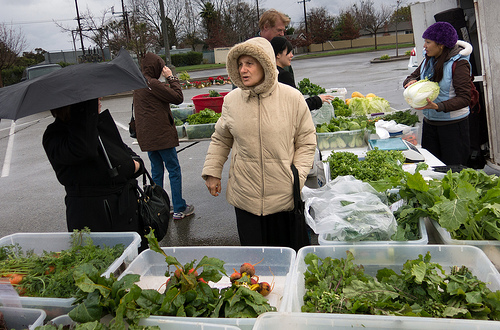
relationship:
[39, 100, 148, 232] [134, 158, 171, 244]
woman carrying a bags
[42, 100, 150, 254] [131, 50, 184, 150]
woman has coat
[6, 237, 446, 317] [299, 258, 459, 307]
bins filled with vegetables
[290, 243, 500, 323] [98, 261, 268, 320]
bins full of radish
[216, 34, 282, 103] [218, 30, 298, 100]
fur around hood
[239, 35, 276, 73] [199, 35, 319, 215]
hood of jacket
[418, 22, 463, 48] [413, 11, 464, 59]
cap on head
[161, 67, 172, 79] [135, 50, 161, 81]
hand raised to head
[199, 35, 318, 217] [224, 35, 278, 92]
jacket has hood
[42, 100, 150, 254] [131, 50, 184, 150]
woman wearing coat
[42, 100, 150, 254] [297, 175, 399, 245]
woman carrying bag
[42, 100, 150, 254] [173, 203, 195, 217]
woman wearing sneaker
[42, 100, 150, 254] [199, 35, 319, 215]
woman wearing jacket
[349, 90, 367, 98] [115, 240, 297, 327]
vegetable inside bin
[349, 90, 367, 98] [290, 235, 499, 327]
vegetable inside bin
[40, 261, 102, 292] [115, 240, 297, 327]
vegetable inside bin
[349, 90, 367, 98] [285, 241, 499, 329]
vegetable inside plastic bin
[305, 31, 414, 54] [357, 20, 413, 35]
fence in front of house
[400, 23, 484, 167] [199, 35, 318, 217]
woman wearing jacket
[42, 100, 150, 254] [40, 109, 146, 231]
woman wearing black jacket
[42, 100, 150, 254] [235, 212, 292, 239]
woman wearing pants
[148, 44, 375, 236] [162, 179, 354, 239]
woman wearing jeans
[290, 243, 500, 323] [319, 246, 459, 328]
bins of leaves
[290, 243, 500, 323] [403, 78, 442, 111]
bins of fruits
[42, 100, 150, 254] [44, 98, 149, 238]
woman wearing coat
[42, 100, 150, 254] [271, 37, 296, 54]
woman with black hair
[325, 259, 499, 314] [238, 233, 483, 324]
leaves in bin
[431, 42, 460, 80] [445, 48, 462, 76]
hair laying over shoulder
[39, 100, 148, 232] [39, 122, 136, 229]
woman wearing coat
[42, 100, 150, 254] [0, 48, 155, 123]
woman carrying umbrella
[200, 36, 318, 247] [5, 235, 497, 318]
woman at stand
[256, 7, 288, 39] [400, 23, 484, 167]
man talking to woman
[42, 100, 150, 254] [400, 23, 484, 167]
woman talking to woman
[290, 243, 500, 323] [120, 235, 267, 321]
bins of plants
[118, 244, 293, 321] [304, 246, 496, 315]
bucket of plants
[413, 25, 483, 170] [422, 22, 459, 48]
woman wearing a cap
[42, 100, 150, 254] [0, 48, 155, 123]
woman holding umbrella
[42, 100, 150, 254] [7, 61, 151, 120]
woman standing under umbrella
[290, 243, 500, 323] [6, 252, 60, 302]
bins of carrots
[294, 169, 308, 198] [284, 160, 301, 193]
hand in pocket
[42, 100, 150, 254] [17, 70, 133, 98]
woman holding umbrella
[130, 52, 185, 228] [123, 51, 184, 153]
woman wearing brown jacket